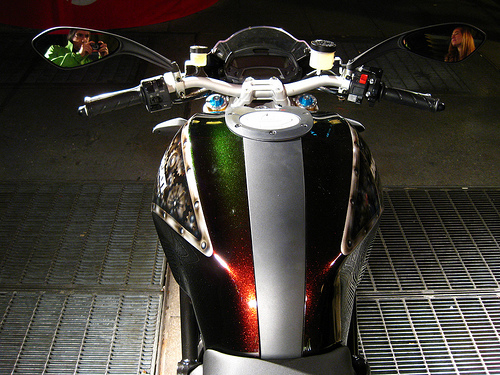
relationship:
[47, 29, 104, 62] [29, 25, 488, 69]
man in mirror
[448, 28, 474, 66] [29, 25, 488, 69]
woman in mirror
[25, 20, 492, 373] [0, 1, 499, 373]
motorcycle on street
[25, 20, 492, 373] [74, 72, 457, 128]
motorcycle has handlebars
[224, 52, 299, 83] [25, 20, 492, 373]
meter on motorcycle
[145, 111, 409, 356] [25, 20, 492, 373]
tank on motorcycle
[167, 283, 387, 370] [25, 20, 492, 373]
shocks on motorcycle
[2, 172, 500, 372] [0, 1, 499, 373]
grill on street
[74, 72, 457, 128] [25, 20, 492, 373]
handlebars on motorcycle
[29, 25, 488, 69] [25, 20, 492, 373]
mirror on motorcycle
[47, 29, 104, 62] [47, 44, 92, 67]
man in jacket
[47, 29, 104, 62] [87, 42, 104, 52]
man holding camera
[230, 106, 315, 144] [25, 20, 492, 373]
cap on motorcycle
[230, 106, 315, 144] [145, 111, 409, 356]
cap on tank